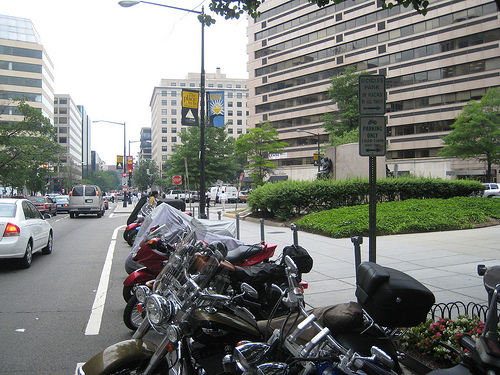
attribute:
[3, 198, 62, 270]
car — small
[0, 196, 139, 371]
road — silver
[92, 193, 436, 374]
bikes — parked, off, red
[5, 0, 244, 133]
sky — huge, white, bright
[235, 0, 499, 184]
building — black, close, massive, wide, brown, tall, white